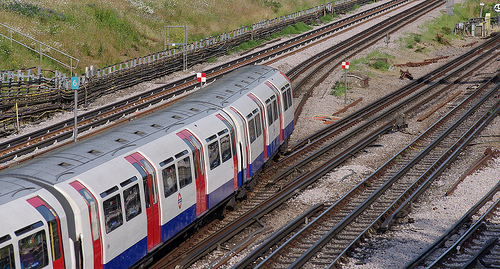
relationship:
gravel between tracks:
[337, 134, 495, 267] [141, 37, 483, 266]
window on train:
[177, 150, 194, 188] [2, 65, 294, 267]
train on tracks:
[2, 65, 294, 267] [0, 1, 499, 264]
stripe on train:
[188, 173, 256, 221] [6, 53, 312, 258]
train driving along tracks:
[2, 65, 294, 267] [292, 2, 452, 129]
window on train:
[177, 150, 194, 188] [3, 26, 308, 266]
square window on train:
[242, 109, 265, 145] [50, 59, 300, 263]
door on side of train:
[124, 156, 178, 242] [6, 57, 420, 261]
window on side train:
[78, 185, 102, 242] [2, 65, 294, 267]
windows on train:
[99, 173, 146, 234] [2, 65, 294, 267]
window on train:
[20, 235, 45, 265] [55, 83, 319, 224]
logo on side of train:
[175, 192, 185, 209] [2, 65, 294, 267]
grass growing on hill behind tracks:
[3, 5, 330, 82] [0, 1, 499, 264]